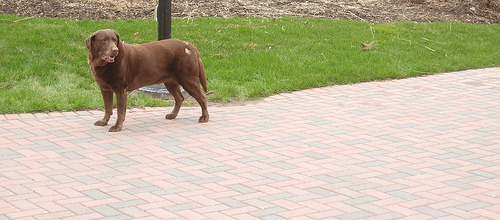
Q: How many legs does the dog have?
A: 4.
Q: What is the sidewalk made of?
A: Brick.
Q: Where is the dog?
A: Standing on the sidewalk.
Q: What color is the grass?
A: Green.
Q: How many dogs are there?
A: 1.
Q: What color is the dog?
A: Brown.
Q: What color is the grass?
A: Green.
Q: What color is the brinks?
A: Pink and gray.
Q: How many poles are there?
A: 1.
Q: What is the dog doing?
A: Standing.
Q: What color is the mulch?
A: Brown.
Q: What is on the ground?
A: Bricks.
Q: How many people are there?
A: None.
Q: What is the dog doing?
A: Looking back.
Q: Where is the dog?
A: Standing on the pavement.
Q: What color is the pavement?
A: Red and black.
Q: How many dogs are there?
A: One.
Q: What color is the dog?
A: Brown.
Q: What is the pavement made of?
A: Brick.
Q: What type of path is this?
A: A stone brick one.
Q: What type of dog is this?
A: A large brown retriever.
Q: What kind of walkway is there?
A: Brick.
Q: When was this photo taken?
A: Daytime.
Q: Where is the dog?
A: On the walkway.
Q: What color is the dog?
A: Brown.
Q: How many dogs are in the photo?
A: One.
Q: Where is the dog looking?
A: To its left.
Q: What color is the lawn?
A: Green.